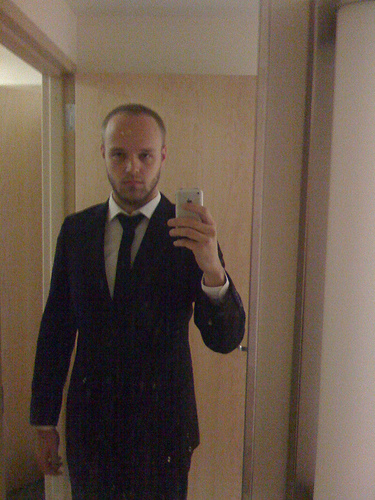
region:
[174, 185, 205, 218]
part of a white cellphone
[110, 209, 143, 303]
part of a black tie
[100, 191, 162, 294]
part of a man's white shirt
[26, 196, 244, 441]
a man's black suit coat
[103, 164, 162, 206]
a man's beard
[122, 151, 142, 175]
the nose of a man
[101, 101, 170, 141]
a man's short cut hair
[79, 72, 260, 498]
part of a brown door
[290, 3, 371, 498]
part of a white painted wall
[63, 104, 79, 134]
a silver door hinge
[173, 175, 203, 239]
i phone in a man's hand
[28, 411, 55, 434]
dress shirt peaking out from under a suit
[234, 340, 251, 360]
silver door handle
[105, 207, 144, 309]
black tie on a man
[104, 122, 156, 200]
face on a man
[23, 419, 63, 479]
empty hand on a man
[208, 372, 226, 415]
light wood on a door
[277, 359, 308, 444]
open door to a hallway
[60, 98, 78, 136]
silver door jam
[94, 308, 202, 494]
dirt on a mirror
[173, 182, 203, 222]
a silver back to an iphone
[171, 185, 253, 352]
a hand holding an iphone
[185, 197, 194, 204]
a black apple logo on an iphone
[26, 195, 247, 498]
a black suit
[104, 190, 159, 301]
a white collared shirt and tie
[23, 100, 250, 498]
a man in a black suit taking a selfie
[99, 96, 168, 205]
a man with short cropped hair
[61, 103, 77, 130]
a white door hinge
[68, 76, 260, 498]
a brown wooden door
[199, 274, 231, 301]
the sleeve of a white shirt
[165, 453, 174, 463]
spot on dirty mirror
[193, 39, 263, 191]
mirror edge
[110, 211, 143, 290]
tie for professionalism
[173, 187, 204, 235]
iphone mobile device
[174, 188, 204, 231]
designed by Apple in California, assembled in China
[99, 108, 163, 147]
receding hairline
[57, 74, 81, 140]
door hinge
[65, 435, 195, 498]
dress slacks for dressy occasions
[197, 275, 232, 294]
wrist cuffs buttoned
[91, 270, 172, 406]
dress jacket for fancy occasions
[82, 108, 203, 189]
the head of a man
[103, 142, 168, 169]
the eyes of a man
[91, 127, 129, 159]
the ear of a man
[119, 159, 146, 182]
the nose of a man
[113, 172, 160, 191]
the lips of a man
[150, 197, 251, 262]
the hand of a man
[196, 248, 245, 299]
the wrist of a man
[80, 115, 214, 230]
the face of a man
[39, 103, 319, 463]
a man wearing a suit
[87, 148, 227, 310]
a man wearing a tie